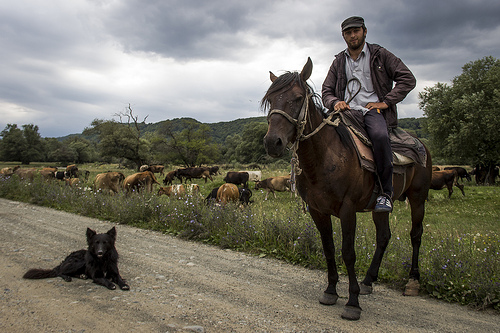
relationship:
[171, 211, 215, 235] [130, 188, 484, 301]
flowers in front of grass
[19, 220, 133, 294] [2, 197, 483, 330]
dog on ground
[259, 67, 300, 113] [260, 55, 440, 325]
hair of horse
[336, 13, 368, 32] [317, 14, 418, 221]
hat of man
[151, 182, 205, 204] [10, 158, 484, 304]
cattle in grass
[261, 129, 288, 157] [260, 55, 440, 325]
nose of horse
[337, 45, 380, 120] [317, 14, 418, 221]
shirt of man